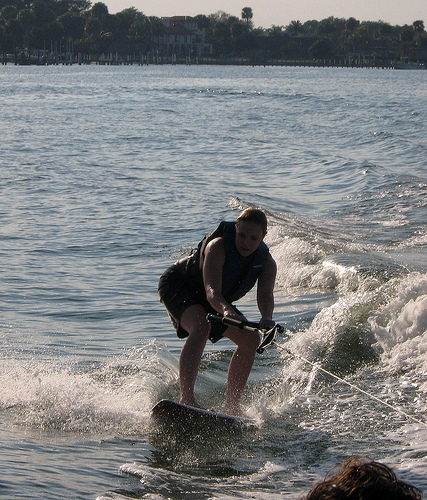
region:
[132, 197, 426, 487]
woman wakeboarding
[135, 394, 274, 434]
wakeboard sticking out of the water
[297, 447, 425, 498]
top of someone's head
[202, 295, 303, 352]
hands holding onto the handlebar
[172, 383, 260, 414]
both feet on the board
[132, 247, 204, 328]
butt is sticking out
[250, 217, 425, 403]
small wave in the water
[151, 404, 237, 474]
water is splashing up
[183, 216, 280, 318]
person is wearing a life jacket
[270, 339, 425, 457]
string running from the woman to the boat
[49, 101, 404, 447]
This is along a lake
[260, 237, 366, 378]
The wave crests are white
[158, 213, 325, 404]
the person is surfing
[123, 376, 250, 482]
this is a board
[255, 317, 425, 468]
this is a line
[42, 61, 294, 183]
the waver is blue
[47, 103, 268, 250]
the water is calm here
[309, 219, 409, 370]
the water is rough here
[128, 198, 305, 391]
this is a woman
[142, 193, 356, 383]
the woman has a life vest on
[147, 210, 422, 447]
woman on a jet skii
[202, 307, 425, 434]
handle and wire of jet skii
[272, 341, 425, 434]
wire of jet skii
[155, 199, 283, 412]
woman is crouching over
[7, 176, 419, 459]
white waves created from jet skii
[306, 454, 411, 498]
top of a person's hair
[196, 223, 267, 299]
black life vest on the woman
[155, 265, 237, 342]
black swim shorts on the woman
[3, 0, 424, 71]
trees and buildings in the distance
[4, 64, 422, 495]
large body of water for jet skiing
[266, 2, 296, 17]
this is the sky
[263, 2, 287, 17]
the sky is full of clouds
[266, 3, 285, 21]
the clouds are white in color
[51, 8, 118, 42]
these are some trees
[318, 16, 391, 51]
the trees are tall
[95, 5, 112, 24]
the leaves are green in color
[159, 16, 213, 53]
this is a building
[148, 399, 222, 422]
this is a surfboard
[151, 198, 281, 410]
the woman is surfing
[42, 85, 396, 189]
this is some water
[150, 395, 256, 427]
The board the person is on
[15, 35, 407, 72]
The poles coming out of the water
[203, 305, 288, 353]
The handle at the end of the rope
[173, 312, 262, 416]
The boarder's bare legs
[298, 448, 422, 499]
The hair of the person watching the boarder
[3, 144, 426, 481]
The wake behind the boat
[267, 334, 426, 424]
The rope connected to the handle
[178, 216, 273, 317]
The woman's life vest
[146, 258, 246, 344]
The shorts of the woman boarding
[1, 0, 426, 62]
Trees on the shoreline